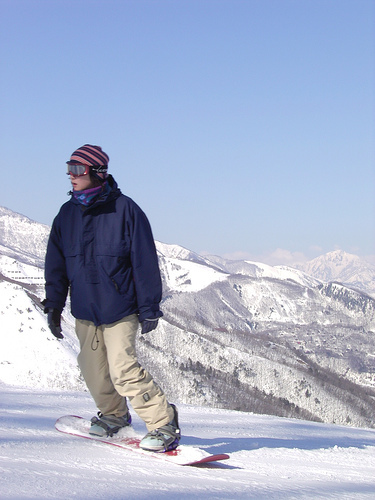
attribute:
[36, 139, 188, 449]
man — snowboarding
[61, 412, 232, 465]
snowboard — red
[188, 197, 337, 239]
clouds — white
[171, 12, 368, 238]
sky — blue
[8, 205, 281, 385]
hills — snowy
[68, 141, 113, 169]
cap — striped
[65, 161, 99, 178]
goggles — red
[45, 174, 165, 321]
jacket — blue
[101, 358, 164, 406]
knee — bent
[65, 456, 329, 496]
snow — white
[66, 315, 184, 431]
pants — brown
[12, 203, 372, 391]
landscape — mountainous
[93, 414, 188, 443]
shoes — gray